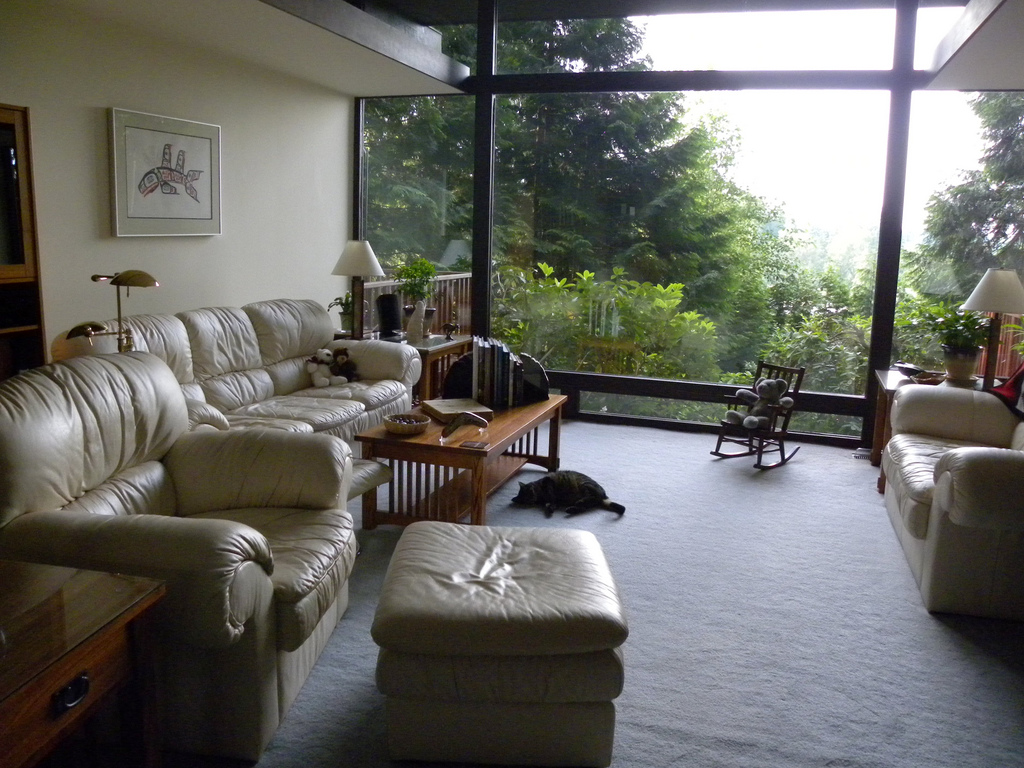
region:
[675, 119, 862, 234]
a view of sky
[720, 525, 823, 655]
a view of floor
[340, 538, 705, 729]
a view of chair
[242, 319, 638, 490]
a view of table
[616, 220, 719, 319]
a view of trees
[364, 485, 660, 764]
the beige leather ottoman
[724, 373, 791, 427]
the teddy bear on the rocking chair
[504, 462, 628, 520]
the cat is relaxing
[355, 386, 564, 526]
the coffee table is wooden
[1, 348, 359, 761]
the beige leather arm chair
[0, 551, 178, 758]
the side table is wooden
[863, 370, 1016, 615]
the beige leather love seat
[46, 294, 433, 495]
the beige leather sofa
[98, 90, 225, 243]
the painting on the wall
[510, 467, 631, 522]
cat laying on living room floor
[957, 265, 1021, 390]
lamp sits on top of an end table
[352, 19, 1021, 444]
large windows in a living room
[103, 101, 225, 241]
picture hanging on the wall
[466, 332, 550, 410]
books lined up on a coffee table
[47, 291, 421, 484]
off white leather couch in a living room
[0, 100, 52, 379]
wooden curio cabinet in the living room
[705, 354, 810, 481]
Child rocking chair with teddy bear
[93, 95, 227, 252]
Picture of fish on the wall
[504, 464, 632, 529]
Cat sleeping on the floor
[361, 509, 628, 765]
Tan upholstered ottoman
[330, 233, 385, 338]
Lamp on the end table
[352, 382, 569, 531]
Coffee table in front of the couch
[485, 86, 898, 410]
Large picture window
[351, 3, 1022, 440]
Trees outside the window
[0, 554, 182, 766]
Wood end table with drawer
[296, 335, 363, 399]
Two teddy bears on the couch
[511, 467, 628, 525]
Black cat laying on floor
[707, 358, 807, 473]
Rocking chair in front of picture window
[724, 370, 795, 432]
Stuffed animal sitting in rocking chair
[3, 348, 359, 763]
Overstuffed white leather armchair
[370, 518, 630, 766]
Overstuffed white leather ottoman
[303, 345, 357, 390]
Stuffed animals on white couch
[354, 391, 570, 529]
Brown wooden coffee table with books on it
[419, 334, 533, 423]
Books on wooden coffee table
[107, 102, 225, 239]
Picture of fish hanging on wall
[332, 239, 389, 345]
Tall table lamp with white shade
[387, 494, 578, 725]
a foot stool that is white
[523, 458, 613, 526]
a cat that is black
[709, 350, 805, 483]
a rocking chair that is wooden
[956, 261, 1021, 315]
a lamp shade that is white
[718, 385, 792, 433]
a teddy bear that is grey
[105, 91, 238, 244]
a picture that is white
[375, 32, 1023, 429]
a large window in the house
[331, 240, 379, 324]
a small white lamp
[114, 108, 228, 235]
a picture on the wall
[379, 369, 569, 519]
a wooden coffee table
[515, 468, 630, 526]
a cat laying on the floor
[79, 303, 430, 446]
a large white sofa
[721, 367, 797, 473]
a small rocking chair with a teddy bear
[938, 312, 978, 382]
a plant in a pot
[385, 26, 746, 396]
trees outside of a window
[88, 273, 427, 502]
A creamed color leather sofa.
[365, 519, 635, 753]
A cream color leather ottoman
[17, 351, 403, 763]
A cream colored armchair.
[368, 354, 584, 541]
A wooden brown coffee table